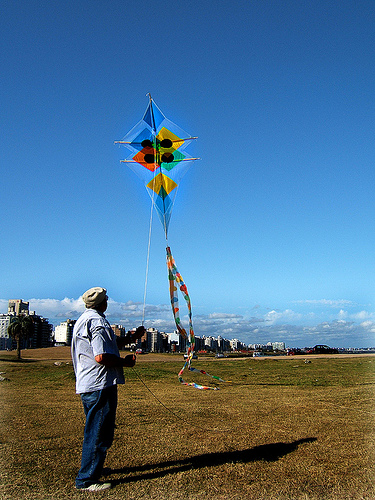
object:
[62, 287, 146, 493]
man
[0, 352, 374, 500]
grass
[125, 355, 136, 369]
hand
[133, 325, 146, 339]
hand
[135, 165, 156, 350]
string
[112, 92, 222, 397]
kite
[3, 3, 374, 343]
sky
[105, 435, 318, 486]
shadow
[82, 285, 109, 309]
cap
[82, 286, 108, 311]
head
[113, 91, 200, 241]
design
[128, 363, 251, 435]
line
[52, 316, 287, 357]
buildings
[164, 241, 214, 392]
tail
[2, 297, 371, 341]
clouds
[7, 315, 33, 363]
palm tree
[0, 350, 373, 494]
ground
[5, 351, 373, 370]
landscape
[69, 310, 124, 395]
shirt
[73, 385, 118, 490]
jeans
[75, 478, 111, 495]
sneakers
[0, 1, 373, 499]
background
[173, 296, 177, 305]
dots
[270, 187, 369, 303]
air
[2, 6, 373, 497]
wind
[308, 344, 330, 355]
car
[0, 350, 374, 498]
park